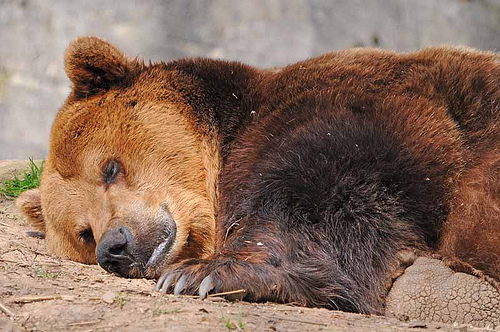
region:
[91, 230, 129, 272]
Black nose of a brown and black bear.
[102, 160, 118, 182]
A bears left eye.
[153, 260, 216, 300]
Sharp grey claws on a bear.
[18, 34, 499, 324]
A brown and black bear lying down.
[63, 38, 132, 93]
A bears left side ear.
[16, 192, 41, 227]
Ear on a bear almost touching the ground.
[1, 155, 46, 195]
Small green grass patch by a bears head.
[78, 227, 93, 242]
Eye of a bear close to the ground.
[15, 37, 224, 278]
Brown head of a bear lying down.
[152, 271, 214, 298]
Four grey claws on a bears hand.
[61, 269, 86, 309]
part of a ground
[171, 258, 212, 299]
edge of a paw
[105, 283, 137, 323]
part of a ground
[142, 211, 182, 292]
part of a mouth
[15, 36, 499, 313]
a large brown bear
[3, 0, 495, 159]
blurred background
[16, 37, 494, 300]
the bears eyes are closed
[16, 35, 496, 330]
the bear is laying on the bar ground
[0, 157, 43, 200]
small patch of green grass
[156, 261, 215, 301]
four gray claws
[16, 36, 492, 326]
fuzzy brown bear with dark brown spots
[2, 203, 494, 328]
twigs and straw on the bare ground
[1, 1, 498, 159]
gray colored, blurred background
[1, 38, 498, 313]
small patch of green grass behind the bear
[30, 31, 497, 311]
brown bear taking a rest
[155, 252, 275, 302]
bear paw and claws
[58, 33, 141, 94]
ear of a brown bear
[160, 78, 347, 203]
shades of bear fur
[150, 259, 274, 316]
bears paw in dirt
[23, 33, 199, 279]
head of a brown bear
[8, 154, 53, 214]
bear fur and grass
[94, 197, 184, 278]
nose and mouth of a bear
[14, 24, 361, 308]
bear with one eye open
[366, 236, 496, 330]
bottom of a bear's paw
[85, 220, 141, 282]
nose of the bear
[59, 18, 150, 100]
ear of the bear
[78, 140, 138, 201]
eye of the bear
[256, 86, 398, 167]
fur on the bear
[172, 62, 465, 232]
light and dark fur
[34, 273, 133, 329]
dirt under the bear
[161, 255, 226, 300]
claw of the bear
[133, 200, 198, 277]
mouth of the bear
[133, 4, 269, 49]
blurry background of the photo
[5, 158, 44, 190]
grass behind the bear